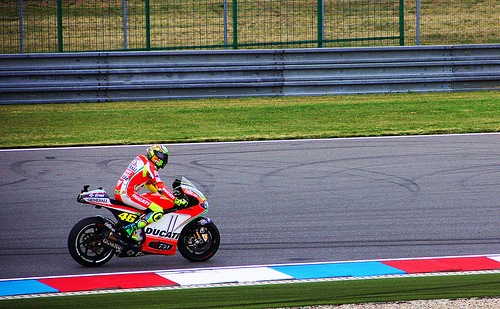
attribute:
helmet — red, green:
[145, 140, 169, 166]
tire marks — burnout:
[1, 140, 499, 260]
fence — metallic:
[1, 0, 499, 55]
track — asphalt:
[2, 133, 499, 277]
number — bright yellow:
[117, 210, 137, 223]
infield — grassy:
[3, 274, 498, 306]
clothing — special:
[115, 153, 189, 240]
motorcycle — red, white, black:
[72, 182, 228, 263]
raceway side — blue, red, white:
[2, 240, 498, 307]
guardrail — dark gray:
[1, 47, 499, 92]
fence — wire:
[6, 5, 498, 43]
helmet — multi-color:
[144, 140, 174, 170]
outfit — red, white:
[115, 160, 167, 236]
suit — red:
[115, 151, 182, 247]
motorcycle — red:
[79, 182, 219, 260]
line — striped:
[2, 248, 499, 298]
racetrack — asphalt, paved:
[3, 131, 497, 280]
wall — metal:
[0, 39, 499, 110]